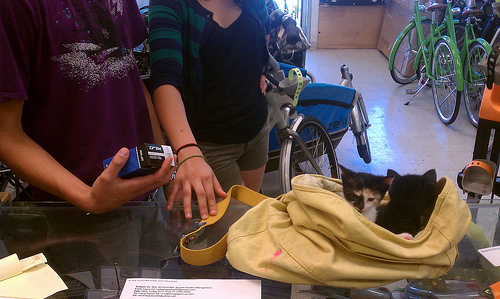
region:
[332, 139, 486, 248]
two kittens in a backpack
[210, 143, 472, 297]
a yellow backpack with kittens in it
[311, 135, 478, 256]
two black kittens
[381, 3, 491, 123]
two green bicycles inside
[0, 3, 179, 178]
a person wearing a purple shirt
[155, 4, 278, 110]
a person wearing a striped sweater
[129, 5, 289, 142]
a person wearing a black shirt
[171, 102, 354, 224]
a person wearing brown shorts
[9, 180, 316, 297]
a glass counter top table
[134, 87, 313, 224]
a person wearing elastics on their wrist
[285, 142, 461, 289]
the kittens are int eh bag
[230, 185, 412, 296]
the bag is yellow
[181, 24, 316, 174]
the shirt is black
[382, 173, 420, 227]
the kittens is black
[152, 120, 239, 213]
the girl is wearing bracelets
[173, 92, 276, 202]
the woman is wearing shorts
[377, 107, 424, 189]
the floor is white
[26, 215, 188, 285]
the table is made of glass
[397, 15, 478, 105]
the bike is green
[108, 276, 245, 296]
the paper is on the table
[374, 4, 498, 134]
A pair of green bicycles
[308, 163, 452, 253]
Two cats in a yellow bag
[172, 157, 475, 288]
A yellow hand bag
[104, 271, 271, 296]
A white piece of paper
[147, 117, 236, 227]
A hand reaching for a handle on a bag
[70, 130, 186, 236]
A hand holding a box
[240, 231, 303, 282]
A red smudge on a handbag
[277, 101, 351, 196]
A metal-spoked wheel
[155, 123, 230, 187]
Bracelets on an arm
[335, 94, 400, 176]
Light reflected on a tile floor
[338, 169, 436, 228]
these are two kittens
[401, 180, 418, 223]
the fur is black in color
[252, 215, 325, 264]
this is a bag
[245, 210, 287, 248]
the bag is brown in color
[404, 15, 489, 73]
these are two bicycles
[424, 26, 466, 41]
the frames are green in color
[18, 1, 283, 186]
these are two people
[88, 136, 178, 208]
the man is holding a box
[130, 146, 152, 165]
the box is blue and black in color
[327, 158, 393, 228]
grey and white kitten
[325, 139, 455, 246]
two kittens in a yellow bag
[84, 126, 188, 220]
hand holding a blue and black box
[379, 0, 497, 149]
two green bikes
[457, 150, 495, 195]
orange rubber foot strap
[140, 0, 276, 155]
green and blue cardigan over a black shirt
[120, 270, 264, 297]
white paper with black writing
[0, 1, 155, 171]
maroon t shirt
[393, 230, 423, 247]
white kitten paw with pink toe pads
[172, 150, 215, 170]
green hair tie wrapped around a wrist